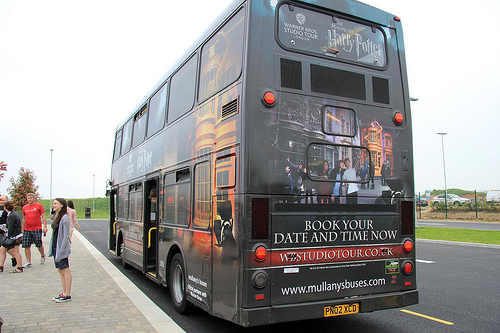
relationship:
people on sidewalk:
[47, 197, 72, 302] [1, 224, 185, 331]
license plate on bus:
[324, 303, 364, 315] [106, 1, 419, 328]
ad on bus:
[275, 101, 397, 296] [106, 1, 419, 328]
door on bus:
[143, 176, 162, 278] [106, 1, 419, 328]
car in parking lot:
[435, 194, 472, 206] [416, 191, 499, 215]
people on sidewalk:
[1, 192, 81, 304] [1, 224, 185, 331]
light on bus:
[263, 92, 277, 104] [106, 1, 419, 328]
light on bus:
[393, 112, 407, 126] [106, 1, 419, 328]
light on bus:
[256, 246, 268, 263] [106, 1, 419, 328]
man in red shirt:
[23, 192, 50, 271] [22, 205, 46, 232]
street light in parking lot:
[437, 130, 450, 220] [416, 191, 499, 215]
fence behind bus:
[418, 191, 500, 221] [106, 1, 419, 328]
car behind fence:
[435, 194, 472, 206] [418, 191, 500, 221]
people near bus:
[1, 192, 81, 304] [106, 1, 419, 328]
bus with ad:
[106, 1, 419, 328] [275, 101, 397, 296]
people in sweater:
[47, 197, 72, 302] [49, 214, 71, 258]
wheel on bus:
[166, 250, 190, 310] [106, 1, 419, 328]